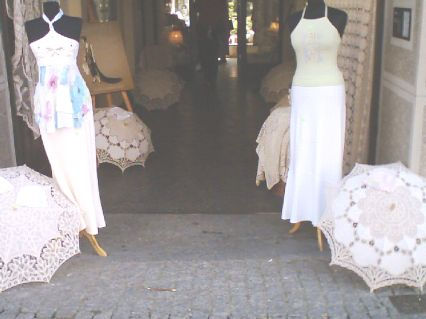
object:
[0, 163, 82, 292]
umbrella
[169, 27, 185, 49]
light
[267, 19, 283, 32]
light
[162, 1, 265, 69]
doorway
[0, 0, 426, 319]
store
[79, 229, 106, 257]
wood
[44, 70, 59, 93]
design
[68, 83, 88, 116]
design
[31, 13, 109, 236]
dress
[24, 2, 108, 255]
dummy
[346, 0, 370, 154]
wall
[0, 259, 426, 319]
cobblestones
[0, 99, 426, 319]
ground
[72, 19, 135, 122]
easel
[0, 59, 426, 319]
sidewalk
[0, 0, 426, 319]
building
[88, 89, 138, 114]
stand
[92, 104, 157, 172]
umbrella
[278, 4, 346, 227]
dress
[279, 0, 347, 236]
dummy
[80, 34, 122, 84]
woman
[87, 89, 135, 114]
wooden structure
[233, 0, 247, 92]
pillar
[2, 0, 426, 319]
room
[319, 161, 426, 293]
umbrella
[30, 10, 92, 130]
tank